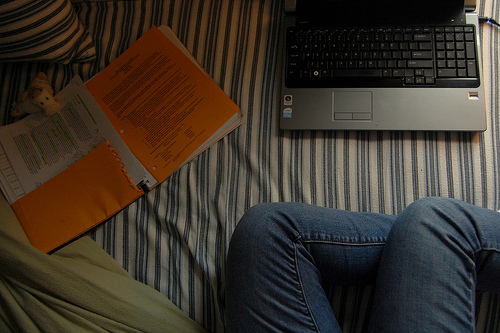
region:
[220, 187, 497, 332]
a person's legs in blue jeans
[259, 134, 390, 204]
striped sheet on the bed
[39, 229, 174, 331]
pale green blacket laid on the bed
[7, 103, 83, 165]
black text with higlighted lines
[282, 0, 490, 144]
grey and black laptop computer on the bed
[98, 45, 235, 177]
orange paper with black lettering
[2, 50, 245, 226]
an orange folder filled with papers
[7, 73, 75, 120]
a small stuff cow on the bed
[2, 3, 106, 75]
striped pillow on the bed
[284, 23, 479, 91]
black keyboard of the laptop computer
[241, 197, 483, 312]
the jeans are blue in color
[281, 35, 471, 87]
the keys are blackin color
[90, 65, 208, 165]
the paper is orange in color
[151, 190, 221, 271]
the sheet is grey and white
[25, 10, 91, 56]
the pillow is black and white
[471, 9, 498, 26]
the cable is in the laptop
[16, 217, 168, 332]
the sheet is brown in color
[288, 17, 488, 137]
the laptop is silver in color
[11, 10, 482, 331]
the scene is in the bedroom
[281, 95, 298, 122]
stickers are on the laptop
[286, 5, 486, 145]
A laptop kept in the bed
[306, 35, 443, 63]
Black color keyboard of the laptop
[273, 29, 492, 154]
Silver and black color of the laptop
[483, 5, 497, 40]
Black color charger wire in the laptop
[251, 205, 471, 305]
A person wearing blue color jean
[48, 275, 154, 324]
A person wearing cream color dress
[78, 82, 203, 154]
Some booklets near the person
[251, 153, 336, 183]
White and black color of the bedsheet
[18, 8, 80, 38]
Pillow kept in the bed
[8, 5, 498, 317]
A person with laptop and booklets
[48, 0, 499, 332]
Striped sheet on a bed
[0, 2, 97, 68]
A white and blue striped pillowcase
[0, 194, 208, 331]
A light green blanket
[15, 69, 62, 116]
A small stuffed animal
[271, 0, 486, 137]
A open laptop computer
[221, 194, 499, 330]
Bent legs in blue jeans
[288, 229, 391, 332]
The inseam of a pair of pants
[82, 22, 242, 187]
An orange piece of paper with typed words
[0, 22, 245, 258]
An orange folder holding papers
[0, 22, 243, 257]
A stack of papers laying on a bed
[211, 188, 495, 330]
legs of a person wearing blue jeans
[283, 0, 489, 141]
grey laptop computer sitting on the bed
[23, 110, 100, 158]
black text with highlighted lines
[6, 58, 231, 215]
an orange folder filled with papers on the bed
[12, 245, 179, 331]
pale green comforter laid on the bed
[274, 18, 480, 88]
black keyboard of the laptop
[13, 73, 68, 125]
small stuffed cow on the bed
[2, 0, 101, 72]
striped pillow sitting on the bed